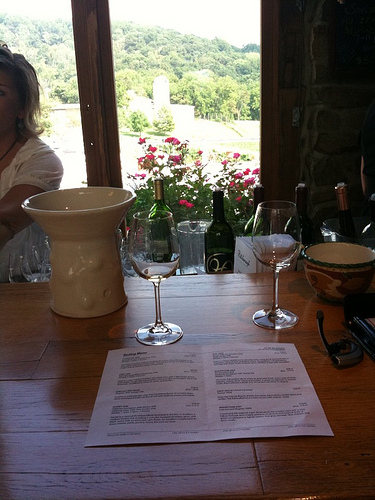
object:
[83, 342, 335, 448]
menu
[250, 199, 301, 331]
wine glass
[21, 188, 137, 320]
vase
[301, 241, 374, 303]
bowl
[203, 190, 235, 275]
wine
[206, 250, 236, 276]
lable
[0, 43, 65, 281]
woman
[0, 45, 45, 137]
hair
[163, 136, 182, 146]
rose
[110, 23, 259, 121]
hill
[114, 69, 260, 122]
trees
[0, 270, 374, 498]
table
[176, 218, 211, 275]
pitcher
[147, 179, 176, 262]
wine bottle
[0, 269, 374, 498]
talbe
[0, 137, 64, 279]
shirt